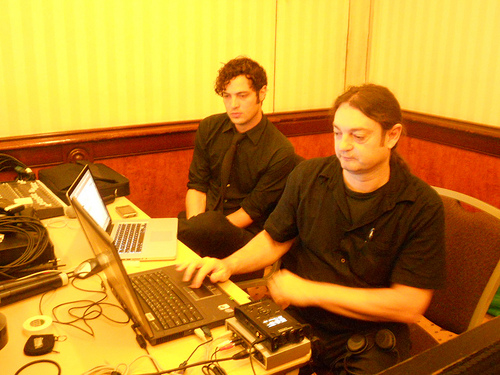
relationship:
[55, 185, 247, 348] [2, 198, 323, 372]
laptop on desk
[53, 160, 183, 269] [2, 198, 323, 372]
laptop on desk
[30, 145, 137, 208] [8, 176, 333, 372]
laptop bag on desk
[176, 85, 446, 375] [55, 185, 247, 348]
man looks laptop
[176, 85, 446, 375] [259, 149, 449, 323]
man wears shirt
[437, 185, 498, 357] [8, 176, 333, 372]
chair next desk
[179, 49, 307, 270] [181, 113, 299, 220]
man wears shirt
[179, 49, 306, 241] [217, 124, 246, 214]
man wears tie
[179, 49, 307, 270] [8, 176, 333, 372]
man at desk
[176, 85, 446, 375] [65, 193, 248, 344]
man look laptop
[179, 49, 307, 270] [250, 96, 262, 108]
man has burn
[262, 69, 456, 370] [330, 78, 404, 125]
man has hair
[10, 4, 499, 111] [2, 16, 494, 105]
wall has stripes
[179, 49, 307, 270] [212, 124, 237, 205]
man has tie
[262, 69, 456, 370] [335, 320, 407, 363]
man has headphones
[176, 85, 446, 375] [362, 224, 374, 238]
man has pen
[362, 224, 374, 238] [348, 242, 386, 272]
pen in pocket